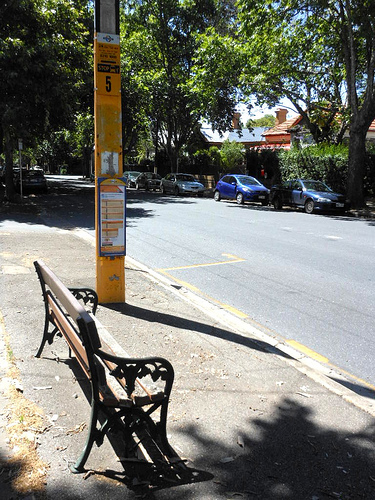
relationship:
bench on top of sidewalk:
[23, 256, 187, 478] [2, 192, 372, 499]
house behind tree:
[265, 90, 372, 152] [231, 1, 374, 208]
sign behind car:
[93, 32, 121, 100] [263, 175, 351, 217]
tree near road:
[231, 1, 374, 208] [37, 168, 374, 383]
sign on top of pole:
[93, 32, 121, 100] [86, 3, 136, 312]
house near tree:
[265, 90, 372, 152] [231, 1, 374, 208]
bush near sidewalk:
[267, 141, 373, 193] [2, 192, 372, 499]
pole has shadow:
[86, 3, 136, 312] [103, 294, 374, 402]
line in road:
[154, 246, 247, 283] [37, 168, 374, 383]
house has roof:
[265, 90, 372, 152] [257, 104, 317, 138]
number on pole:
[101, 72, 115, 95] [86, 3, 136, 312]